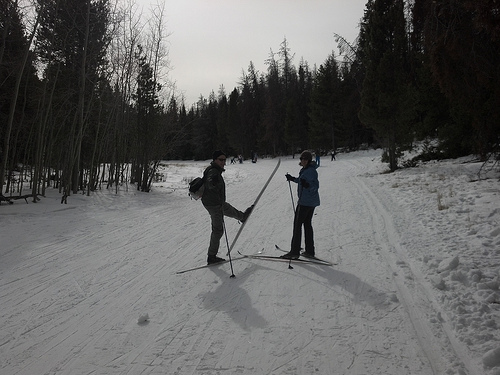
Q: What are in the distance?
A: Trees.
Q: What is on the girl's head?
A: A hat.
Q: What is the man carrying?
A: A bag.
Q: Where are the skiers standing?
A: In the snow.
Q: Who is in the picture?
A: A man and woman.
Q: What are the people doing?
A: Sking.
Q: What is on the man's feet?
A: Skis.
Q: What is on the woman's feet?
A: Skis.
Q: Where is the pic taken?
A: A ski slope.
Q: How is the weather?
A: Cold.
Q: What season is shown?
A: Winter.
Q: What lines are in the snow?
A: Sli tracks.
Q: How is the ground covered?
A: With snow.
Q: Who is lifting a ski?
A: The man.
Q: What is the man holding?
A: Pole.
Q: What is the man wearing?
A: Jacket.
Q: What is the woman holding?
A: Pole.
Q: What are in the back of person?
A: Trees.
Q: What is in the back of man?
A: Trees.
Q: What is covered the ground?
A: Snow.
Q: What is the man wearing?
A: Sunglasses.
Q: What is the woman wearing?
A: Sunglasses.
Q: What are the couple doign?
A: Skiing.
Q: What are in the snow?
A: Marks.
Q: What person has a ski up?
A: Male.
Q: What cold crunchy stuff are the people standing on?
A: Snow.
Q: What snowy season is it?
A: Winter.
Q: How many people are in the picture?
A: 2.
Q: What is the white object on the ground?
A: Snow.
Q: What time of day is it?
A: Day time.